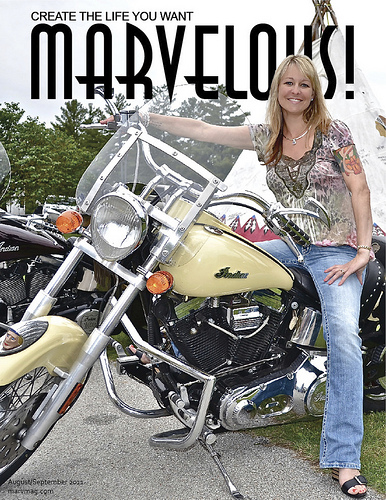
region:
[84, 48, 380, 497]
Lady posing on a motorcycle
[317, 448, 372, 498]
Lady in open toe shoes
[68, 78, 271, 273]
Bug shield attached with nine screws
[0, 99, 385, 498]
Harley Davidson leaning on kick stand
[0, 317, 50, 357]
Ornament on front wheel fender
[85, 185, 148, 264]
Big front head light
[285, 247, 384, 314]
Leather studded seat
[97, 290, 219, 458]
Chrome foot rest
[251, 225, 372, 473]
White washed blue jeans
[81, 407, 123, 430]
Stain in the concrete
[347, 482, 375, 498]
toes in the sandle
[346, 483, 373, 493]
polish on the nails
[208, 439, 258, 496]
kick stand of the cycle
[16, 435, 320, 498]
gravel on the ground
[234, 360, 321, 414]
reflection on the chrome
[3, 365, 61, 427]
spokes on the tire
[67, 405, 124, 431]
stain on the pavement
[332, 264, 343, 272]
ring on womans finger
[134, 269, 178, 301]
light on the bike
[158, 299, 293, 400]
engine of the bike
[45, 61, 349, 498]
a woman sitting on a motorcycle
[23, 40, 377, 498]
a woman posing on a magazine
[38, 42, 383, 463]
a woman sitting on bike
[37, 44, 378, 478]
a woman sitting on a yellow motorcycle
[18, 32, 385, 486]
a woman sitting on a pale yellow motorcycle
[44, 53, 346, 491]
a woman sitting on a yellow bike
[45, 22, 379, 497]
a woman sitting on a pale yellow bike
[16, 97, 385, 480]
a bike standing up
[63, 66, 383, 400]
a motorcycle standing up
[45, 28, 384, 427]
a woman with one foot on the ground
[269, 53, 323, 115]
A woman with blonde hair smiling into the camera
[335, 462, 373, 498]
A foot with black sandals and red nail polish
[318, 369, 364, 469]
Blue jean pant legs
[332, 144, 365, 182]
A red and green tattoo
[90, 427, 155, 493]
Gray asphalt sidewalk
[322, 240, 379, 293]
A woman's hand on her thigh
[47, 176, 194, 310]
Motorcycle head lights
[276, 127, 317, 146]
A silver necklace around the neck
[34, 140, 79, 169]
Lush green trees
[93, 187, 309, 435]
The body of a motorcycle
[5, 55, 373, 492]
woman sitting on motor bike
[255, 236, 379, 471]
blue jeans on leg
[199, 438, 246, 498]
kick stand on asphalt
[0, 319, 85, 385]
figure of head on fender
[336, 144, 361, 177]
tattoo on woman's arm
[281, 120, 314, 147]
jewelry on woman's neck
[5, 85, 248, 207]
green leaves on trees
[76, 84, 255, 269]
clear windshield on bike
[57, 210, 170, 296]
two orange lights on bike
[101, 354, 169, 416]
shiny curved chrome bar